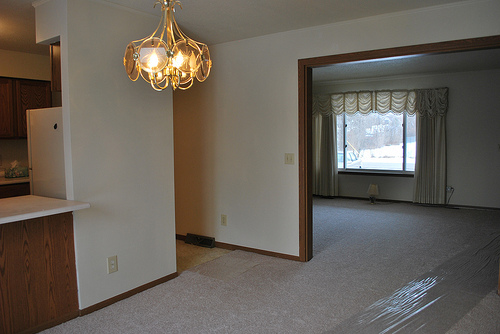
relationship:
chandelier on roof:
[119, 30, 214, 92] [203, 2, 283, 30]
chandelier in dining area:
[123, 0, 213, 93] [0, 0, 498, 330]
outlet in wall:
[101, 250, 121, 282] [68, 0, 177, 309]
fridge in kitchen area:
[26, 107, 68, 200] [1, 1, 64, 196]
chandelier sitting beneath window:
[123, 0, 213, 93] [328, 94, 423, 178]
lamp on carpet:
[367, 183, 379, 204] [33, 186, 499, 332]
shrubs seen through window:
[343, 142, 365, 162] [332, 111, 417, 173]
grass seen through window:
[338, 141, 414, 168] [332, 111, 417, 173]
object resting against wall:
[181, 231, 217, 250] [171, 0, 498, 262]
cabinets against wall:
[2, 73, 63, 148] [228, 85, 282, 150]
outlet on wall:
[106, 255, 118, 275] [96, 243, 125, 275]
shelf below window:
[333, 168, 416, 177] [337, 95, 419, 173]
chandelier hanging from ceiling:
[123, 0, 213, 93] [97, 0, 497, 78]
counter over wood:
[0, 194, 91, 225] [11, 232, 85, 309]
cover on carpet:
[321, 214, 498, 332] [33, 186, 499, 332]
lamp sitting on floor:
[358, 176, 392, 208] [315, 192, 498, 332]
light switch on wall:
[285, 153, 295, 165] [209, 50, 299, 234]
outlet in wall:
[106, 255, 118, 275] [72, 56, 161, 305]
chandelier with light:
[123, 0, 213, 93] [149, 47, 163, 65]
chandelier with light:
[123, 0, 213, 93] [173, 49, 185, 69]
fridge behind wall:
[25, 104, 67, 199] [68, 0, 177, 309]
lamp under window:
[367, 183, 379, 204] [336, 102, 416, 170]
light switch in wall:
[285, 153, 295, 165] [174, 26, 302, 265]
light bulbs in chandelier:
[169, 51, 191, 73] [113, 18, 219, 101]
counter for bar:
[0, 194, 91, 225] [1, 184, 91, 332]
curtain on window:
[312, 88, 450, 205] [334, 98, 421, 174]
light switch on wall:
[280, 151, 300, 168] [174, 26, 302, 265]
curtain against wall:
[312, 88, 450, 205] [310, 65, 497, 210]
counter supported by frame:
[0, 184, 90, 229] [0, 187, 90, 330]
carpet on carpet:
[36, 198, 500, 334] [33, 186, 499, 332]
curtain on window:
[309, 85, 449, 202] [336, 113, 414, 168]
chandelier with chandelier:
[123, 0, 213, 93] [123, 0, 213, 93]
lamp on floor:
[367, 183, 379, 204] [4, 194, 494, 331]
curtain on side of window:
[310, 92, 336, 194] [330, 107, 413, 172]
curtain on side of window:
[415, 90, 450, 204] [330, 107, 413, 172]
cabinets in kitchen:
[0, 76, 53, 139] [0, 1, 87, 224]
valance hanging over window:
[328, 81, 450, 117] [331, 95, 413, 170]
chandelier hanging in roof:
[123, 0, 213, 93] [103, 2, 427, 47]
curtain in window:
[312, 88, 450, 205] [332, 111, 417, 173]